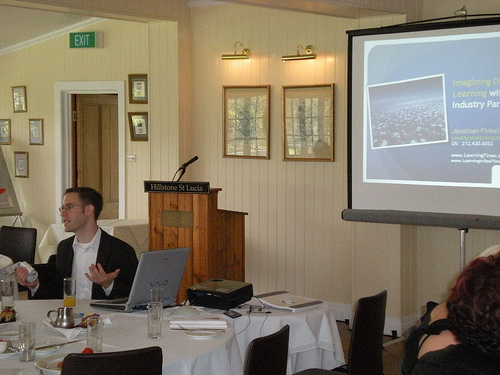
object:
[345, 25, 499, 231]
screen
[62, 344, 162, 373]
chair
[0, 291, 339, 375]
table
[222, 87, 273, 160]
picture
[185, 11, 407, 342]
wall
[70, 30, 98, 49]
sign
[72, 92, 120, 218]
door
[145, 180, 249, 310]
podium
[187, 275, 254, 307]
projecter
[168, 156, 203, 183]
microphone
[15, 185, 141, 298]
man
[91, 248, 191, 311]
laptop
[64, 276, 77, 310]
juice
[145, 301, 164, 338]
glass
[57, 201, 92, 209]
glasses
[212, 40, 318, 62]
light fixtures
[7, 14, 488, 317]
walls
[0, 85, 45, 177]
pictures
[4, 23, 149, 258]
wall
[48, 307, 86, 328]
cup